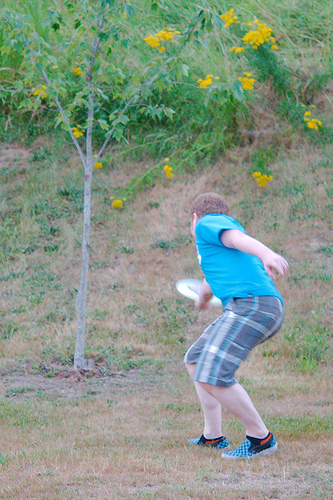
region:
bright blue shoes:
[220, 429, 280, 471]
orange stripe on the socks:
[261, 432, 276, 453]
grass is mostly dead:
[43, 435, 169, 492]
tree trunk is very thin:
[67, 295, 93, 378]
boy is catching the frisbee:
[161, 190, 268, 406]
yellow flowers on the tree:
[251, 91, 323, 186]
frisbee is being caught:
[169, 273, 215, 311]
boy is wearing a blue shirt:
[186, 219, 258, 297]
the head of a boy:
[171, 179, 235, 242]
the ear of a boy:
[189, 202, 224, 241]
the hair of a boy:
[180, 179, 239, 239]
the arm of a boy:
[204, 213, 277, 291]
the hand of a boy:
[250, 239, 310, 289]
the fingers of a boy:
[255, 242, 295, 281]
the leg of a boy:
[201, 325, 306, 453]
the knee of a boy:
[185, 368, 242, 403]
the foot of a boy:
[215, 413, 297, 479]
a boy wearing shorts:
[171, 249, 324, 421]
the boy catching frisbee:
[146, 180, 302, 469]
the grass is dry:
[16, 406, 190, 499]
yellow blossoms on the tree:
[11, 10, 315, 199]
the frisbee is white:
[169, 276, 212, 309]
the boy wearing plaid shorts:
[162, 290, 304, 389]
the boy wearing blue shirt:
[171, 214, 282, 299]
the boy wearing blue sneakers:
[193, 423, 286, 464]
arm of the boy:
[215, 222, 287, 275]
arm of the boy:
[187, 281, 216, 310]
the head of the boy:
[180, 190, 240, 238]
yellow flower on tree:
[245, 160, 277, 198]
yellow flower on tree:
[154, 164, 182, 185]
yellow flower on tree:
[101, 186, 133, 223]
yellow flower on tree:
[85, 157, 105, 173]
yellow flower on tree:
[291, 105, 327, 140]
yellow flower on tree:
[224, 65, 266, 97]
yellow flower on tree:
[189, 65, 228, 99]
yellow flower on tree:
[136, 17, 186, 63]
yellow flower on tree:
[212, 7, 241, 36]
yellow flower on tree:
[26, 74, 52, 108]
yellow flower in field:
[155, 45, 167, 55]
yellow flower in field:
[258, 171, 278, 191]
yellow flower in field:
[109, 195, 133, 211]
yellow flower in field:
[91, 160, 104, 172]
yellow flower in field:
[303, 118, 321, 130]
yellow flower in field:
[265, 38, 279, 52]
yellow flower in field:
[70, 65, 83, 79]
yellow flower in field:
[235, 74, 249, 89]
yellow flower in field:
[256, 33, 268, 46]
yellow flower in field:
[223, 15, 235, 25]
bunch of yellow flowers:
[235, 68, 254, 91]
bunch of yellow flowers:
[249, 170, 273, 189]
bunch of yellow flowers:
[110, 198, 125, 210]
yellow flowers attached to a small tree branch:
[108, 183, 138, 211]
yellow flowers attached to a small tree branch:
[62, 113, 94, 142]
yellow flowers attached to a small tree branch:
[83, 140, 114, 171]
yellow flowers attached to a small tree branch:
[152, 151, 191, 179]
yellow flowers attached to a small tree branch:
[245, 146, 288, 194]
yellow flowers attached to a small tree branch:
[284, 94, 324, 142]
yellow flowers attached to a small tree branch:
[228, 60, 271, 105]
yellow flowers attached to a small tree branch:
[237, 15, 279, 64]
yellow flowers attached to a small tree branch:
[138, 16, 188, 63]